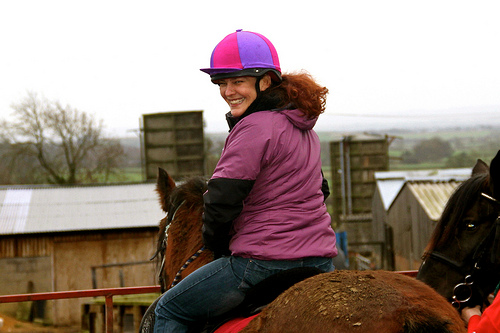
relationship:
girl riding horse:
[141, 20, 340, 331] [135, 150, 450, 330]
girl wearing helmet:
[141, 20, 340, 331] [194, 28, 279, 85]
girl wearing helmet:
[141, 20, 340, 331] [192, 19, 282, 81]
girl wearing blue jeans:
[141, 20, 340, 331] [138, 254, 331, 332]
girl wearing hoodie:
[141, 20, 340, 331] [158, 97, 365, 244]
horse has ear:
[156, 165, 467, 331] [153, 167, 176, 209]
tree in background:
[0, 89, 105, 184] [1, 100, 499, 191]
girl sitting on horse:
[141, 19, 343, 331] [156, 165, 467, 331]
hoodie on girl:
[195, 97, 338, 261] [141, 19, 343, 331]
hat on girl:
[199, 23, 283, 80] [141, 19, 343, 331]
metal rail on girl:
[0, 266, 425, 331] [141, 19, 343, 331]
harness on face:
[166, 246, 208, 282] [145, 165, 204, 283]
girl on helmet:
[141, 20, 340, 331] [200, 26, 280, 78]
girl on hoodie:
[141, 20, 340, 331] [195, 97, 338, 261]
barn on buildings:
[365, 185, 382, 246] [365, 167, 425, 271]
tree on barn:
[0, 89, 105, 184] [1, 176, 215, 327]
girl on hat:
[141, 20, 340, 331] [199, 28, 292, 84]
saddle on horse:
[207, 311, 254, 332] [161, 178, 443, 323]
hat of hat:
[199, 29, 282, 80] [199, 23, 283, 80]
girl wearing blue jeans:
[141, 20, 340, 331] [138, 251, 306, 331]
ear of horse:
[156, 168, 175, 211] [156, 165, 467, 331]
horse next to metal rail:
[156, 165, 467, 331] [0, 266, 425, 331]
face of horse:
[421, 152, 498, 304] [423, 189, 497, 299]